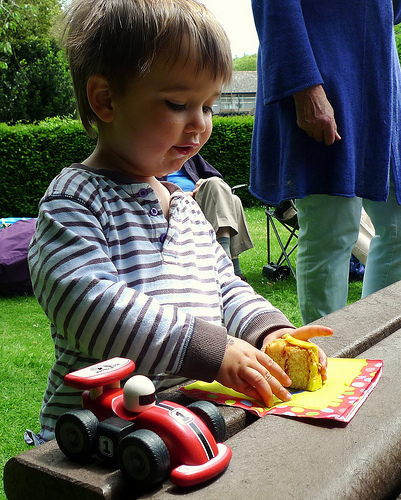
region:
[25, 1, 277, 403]
Little boy eating cake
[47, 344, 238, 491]
Red toy racecar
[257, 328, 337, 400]
White cake with yellow frosting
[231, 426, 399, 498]
Brown picnic table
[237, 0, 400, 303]
Woman in a blue sweater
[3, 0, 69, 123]
Large green tree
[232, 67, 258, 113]
House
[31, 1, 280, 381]
Little boy sitting at picnic table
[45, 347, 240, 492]
Toy racecar sitting on picnic table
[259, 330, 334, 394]
Piece of cake being eaten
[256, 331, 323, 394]
a piece of cake in the child's hands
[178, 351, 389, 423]
a yellow and red napkin underneath the piece of cake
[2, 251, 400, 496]
a bench seat made of recycled materials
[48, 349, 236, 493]
a red plastic toy car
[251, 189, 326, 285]
a folding camping chair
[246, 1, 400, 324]
an adult standing next to the child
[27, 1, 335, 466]
a little boy holding a piece of cake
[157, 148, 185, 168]
food residue on the boy's face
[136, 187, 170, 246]
three buttons on the boy's shirt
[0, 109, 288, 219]
a row of hedges behind the lawn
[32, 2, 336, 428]
young child with a piece of cake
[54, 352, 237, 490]
a red toy race car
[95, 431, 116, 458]
black and white number 1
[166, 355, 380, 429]
a yellow napkin with red trim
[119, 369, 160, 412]
white and black toy helmet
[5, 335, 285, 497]
toy car sitting on a bench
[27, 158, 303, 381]
a long sleeve striped shirt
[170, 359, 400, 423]
polka dots on outside of napkin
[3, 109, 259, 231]
a green trimmed bush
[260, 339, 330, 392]
yellow cake with yellow frosting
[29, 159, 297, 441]
Boy wearing a long sleeved shirt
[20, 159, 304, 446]
Boy wearing a striped long sleeve shirt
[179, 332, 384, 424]
Cake on a napkin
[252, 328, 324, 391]
Cake with yellow frosting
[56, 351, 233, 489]
Toy car on a bench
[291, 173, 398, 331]
Person is wearing pants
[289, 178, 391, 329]
Person is wearing jeans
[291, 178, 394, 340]
Person is wearing blue jeans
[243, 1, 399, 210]
Person is wearing a long shirt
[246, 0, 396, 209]
Person is wearing a long blue shirt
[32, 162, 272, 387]
the shirt is stripes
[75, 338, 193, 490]
a red race car toy